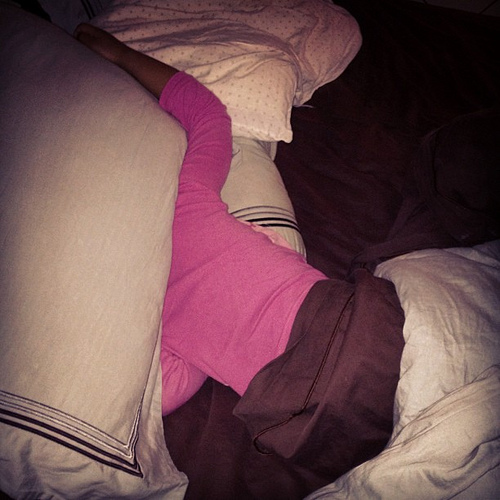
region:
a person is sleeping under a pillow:
[17, 18, 316, 480]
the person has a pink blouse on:
[130, 68, 324, 457]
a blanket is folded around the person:
[163, 267, 403, 494]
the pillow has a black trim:
[11, 301, 176, 497]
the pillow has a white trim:
[2, 374, 171, 464]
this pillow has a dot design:
[108, 2, 373, 152]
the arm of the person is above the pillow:
[71, 20, 241, 211]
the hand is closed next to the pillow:
[61, 15, 134, 75]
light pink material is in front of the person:
[226, 210, 295, 255]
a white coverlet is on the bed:
[313, 247, 495, 498]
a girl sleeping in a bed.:
[2, 0, 498, 475]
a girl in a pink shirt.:
[155, 67, 327, 415]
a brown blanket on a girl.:
[160, 260, 404, 489]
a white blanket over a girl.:
[303, 246, 498, 498]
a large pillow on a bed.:
[0, 0, 196, 497]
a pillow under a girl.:
[204, 143, 309, 250]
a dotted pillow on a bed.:
[98, 0, 367, 148]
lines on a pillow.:
[225, 201, 302, 237]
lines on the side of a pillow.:
[0, 385, 144, 479]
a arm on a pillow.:
[47, 1, 179, 124]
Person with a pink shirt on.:
[65, 0, 440, 477]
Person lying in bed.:
[60, 0, 448, 490]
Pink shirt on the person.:
[125, 65, 335, 423]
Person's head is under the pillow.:
[16, 7, 210, 474]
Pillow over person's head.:
[14, 0, 195, 493]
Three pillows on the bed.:
[31, 0, 294, 474]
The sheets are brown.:
[137, 1, 465, 483]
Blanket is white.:
[331, 226, 492, 497]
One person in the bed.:
[7, 2, 494, 489]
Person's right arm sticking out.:
[66, 14, 246, 219]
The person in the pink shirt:
[77, 19, 406, 435]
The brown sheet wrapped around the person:
[220, 265, 405, 477]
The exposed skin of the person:
[75, 19, 185, 102]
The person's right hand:
[69, 14, 122, 65]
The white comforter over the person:
[309, 231, 499, 499]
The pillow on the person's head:
[0, 6, 190, 499]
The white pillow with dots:
[89, 0, 367, 144]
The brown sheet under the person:
[165, 0, 495, 498]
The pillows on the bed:
[0, 0, 362, 499]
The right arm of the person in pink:
[71, 21, 240, 198]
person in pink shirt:
[42, 24, 422, 496]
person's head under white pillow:
[10, 7, 281, 495]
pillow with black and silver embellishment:
[8, 24, 162, 495]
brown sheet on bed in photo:
[240, 40, 474, 498]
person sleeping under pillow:
[80, 25, 418, 449]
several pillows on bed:
[10, 7, 387, 439]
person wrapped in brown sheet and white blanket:
[311, 185, 463, 496]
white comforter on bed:
[301, 178, 483, 495]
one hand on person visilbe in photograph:
[41, 12, 349, 354]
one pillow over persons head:
[15, 30, 419, 401]